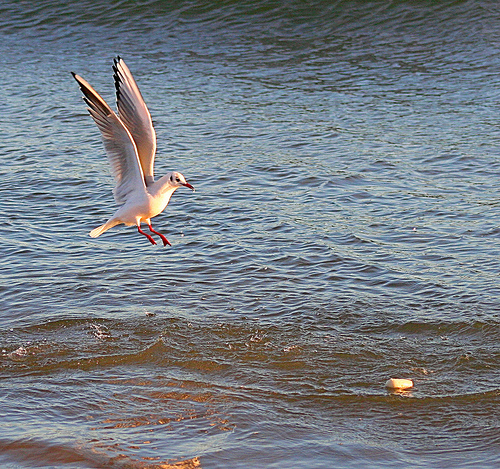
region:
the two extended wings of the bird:
[69, 60, 162, 184]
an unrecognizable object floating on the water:
[384, 376, 411, 388]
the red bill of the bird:
[184, 181, 194, 191]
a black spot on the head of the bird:
[168, 175, 173, 182]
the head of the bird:
[167, 170, 189, 190]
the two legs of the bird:
[138, 226, 173, 245]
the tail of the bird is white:
[88, 218, 117, 237]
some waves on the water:
[39, 326, 266, 431]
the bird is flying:
[18, 20, 385, 334]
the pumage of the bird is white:
[114, 180, 169, 221]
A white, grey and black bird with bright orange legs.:
[68, 54, 196, 247]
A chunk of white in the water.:
[381, 377, 413, 389]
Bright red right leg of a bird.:
[137, 227, 157, 247]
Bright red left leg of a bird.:
[149, 223, 173, 248]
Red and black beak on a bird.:
[181, 180, 196, 190]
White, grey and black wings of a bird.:
[71, 54, 157, 203]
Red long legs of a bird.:
[135, 223, 172, 248]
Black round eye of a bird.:
[174, 177, 181, 183]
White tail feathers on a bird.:
[86, 209, 128, 237]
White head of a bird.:
[164, 170, 186, 191]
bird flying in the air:
[58, 40, 217, 260]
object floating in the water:
[378, 369, 421, 389]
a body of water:
[1, 0, 499, 465]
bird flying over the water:
[68, 53, 220, 290]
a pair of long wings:
[62, 47, 162, 193]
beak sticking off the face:
[182, 182, 197, 193]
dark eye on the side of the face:
[171, 175, 183, 185]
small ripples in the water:
[0, 0, 498, 467]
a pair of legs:
[136, 223, 174, 253]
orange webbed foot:
[161, 237, 173, 249]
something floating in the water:
[377, 370, 422, 396]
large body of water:
[0, 0, 498, 467]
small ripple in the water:
[327, 381, 498, 403]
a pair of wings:
[68, 48, 164, 196]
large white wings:
[71, 50, 158, 193]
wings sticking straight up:
[68, 49, 161, 196]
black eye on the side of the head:
[173, 175, 182, 182]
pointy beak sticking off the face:
[179, 179, 201, 191]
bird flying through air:
[63, 55, 198, 250]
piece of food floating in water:
[381, 368, 412, 389]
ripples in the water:
[5, 302, 476, 458]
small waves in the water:
[1, 1, 496, 317]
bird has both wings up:
[72, 51, 197, 243]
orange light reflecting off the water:
[80, 300, 230, 466]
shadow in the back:
[0, 0, 493, 100]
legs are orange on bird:
[136, 223, 174, 253]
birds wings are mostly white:
[71, 61, 196, 246]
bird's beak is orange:
[179, 180, 198, 195]